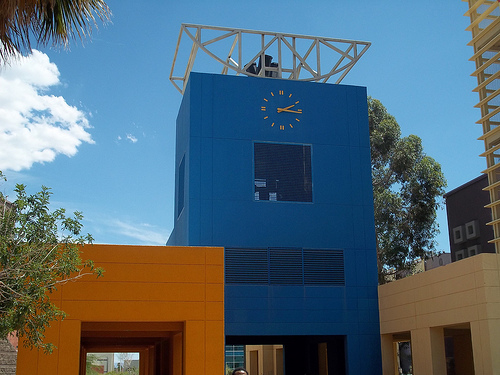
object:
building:
[378, 253, 500, 375]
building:
[443, 171, 500, 263]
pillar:
[166, 72, 381, 375]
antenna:
[169, 23, 371, 95]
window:
[224, 247, 344, 286]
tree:
[0, 172, 106, 353]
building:
[17, 244, 226, 375]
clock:
[262, 90, 303, 130]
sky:
[0, 0, 145, 154]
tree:
[369, 99, 449, 285]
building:
[165, 72, 383, 375]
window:
[465, 220, 481, 239]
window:
[467, 245, 482, 257]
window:
[452, 225, 467, 244]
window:
[455, 249, 464, 260]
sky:
[75, 79, 174, 177]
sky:
[92, 149, 169, 236]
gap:
[225, 336, 346, 375]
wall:
[191, 71, 379, 375]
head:
[259, 55, 273, 66]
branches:
[94, 266, 106, 278]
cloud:
[0, 34, 98, 172]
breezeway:
[80, 321, 185, 374]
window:
[254, 141, 313, 203]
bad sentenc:
[254, 140, 311, 146]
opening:
[80, 321, 187, 374]